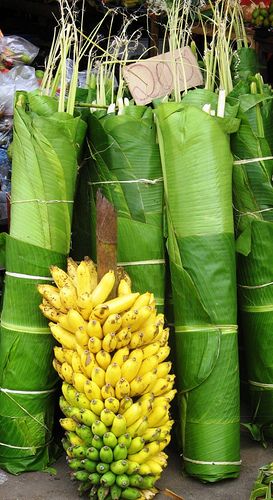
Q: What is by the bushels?
A: Banana trunk.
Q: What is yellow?
A: Banana stalk.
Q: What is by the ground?
A: Ripe bananas.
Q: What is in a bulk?
A: Banana leaves.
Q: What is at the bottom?
A: Banana leaf with bunches.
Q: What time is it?
A: Noon.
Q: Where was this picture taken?
A: Central America.